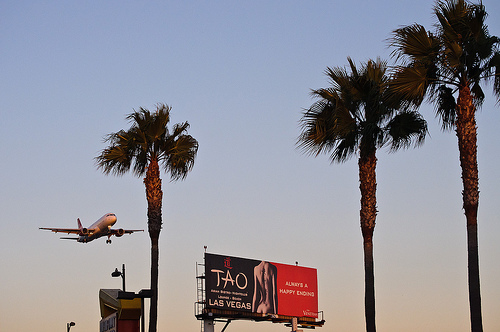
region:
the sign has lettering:
[205, 252, 326, 330]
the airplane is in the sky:
[31, 206, 151, 251]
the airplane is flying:
[41, 208, 148, 240]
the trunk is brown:
[350, 155, 380, 327]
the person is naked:
[250, 255, 285, 316]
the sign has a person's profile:
[200, 252, 322, 323]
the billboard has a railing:
[197, 307, 328, 319]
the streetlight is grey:
[107, 260, 130, 283]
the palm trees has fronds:
[300, 0, 495, 330]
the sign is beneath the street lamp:
[97, 262, 143, 330]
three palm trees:
[91, 0, 496, 326]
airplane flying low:
[36, 208, 151, 243]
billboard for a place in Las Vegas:
[180, 233, 321, 326]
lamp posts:
[61, 260, 139, 327]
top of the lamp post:
[58, 312, 89, 328]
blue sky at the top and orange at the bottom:
[0, 7, 491, 317]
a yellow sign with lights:
[95, 282, 137, 327]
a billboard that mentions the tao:
[186, 247, 322, 323]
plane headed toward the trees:
[40, 206, 140, 247]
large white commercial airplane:
[25, 214, 146, 246]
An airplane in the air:
[35, 206, 147, 246]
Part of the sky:
[18, 31, 62, 51]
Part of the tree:
[341, 80, 363, 102]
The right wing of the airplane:
[35, 221, 82, 231]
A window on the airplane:
[103, 211, 118, 218]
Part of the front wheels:
[104, 235, 111, 245]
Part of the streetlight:
[66, 319, 76, 326]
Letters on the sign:
[211, 265, 250, 290]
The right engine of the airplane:
[78, 225, 88, 235]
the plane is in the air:
[29, 180, 172, 277]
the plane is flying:
[23, 183, 150, 263]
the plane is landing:
[10, 191, 152, 256]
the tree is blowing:
[77, 85, 209, 217]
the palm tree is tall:
[62, 79, 222, 241]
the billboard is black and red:
[150, 233, 337, 325]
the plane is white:
[33, 180, 144, 249]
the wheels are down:
[92, 232, 124, 252]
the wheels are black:
[98, 235, 119, 251]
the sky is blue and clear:
[45, 17, 349, 224]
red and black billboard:
[203, 249, 325, 321]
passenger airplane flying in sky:
[39, 211, 142, 241]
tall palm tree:
[103, 101, 200, 322]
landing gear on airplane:
[100, 231, 113, 243]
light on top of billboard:
[202, 244, 207, 252]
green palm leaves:
[295, 95, 357, 160]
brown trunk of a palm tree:
[356, 157, 391, 326]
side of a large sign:
[86, 283, 139, 329]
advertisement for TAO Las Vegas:
[209, 256, 319, 317]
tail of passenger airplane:
[75, 217, 85, 226]